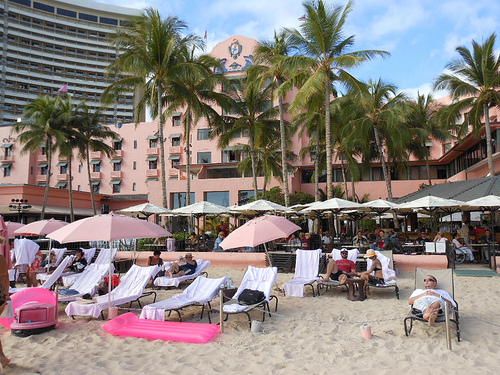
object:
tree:
[9, 95, 96, 224]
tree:
[100, 6, 240, 211]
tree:
[147, 43, 245, 206]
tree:
[388, 88, 470, 188]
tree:
[96, 0, 213, 213]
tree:
[57, 97, 122, 230]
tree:
[329, 70, 412, 205]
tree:
[271, 0, 393, 201]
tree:
[205, 66, 293, 198]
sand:
[0, 267, 500, 375]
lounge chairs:
[206, 265, 280, 332]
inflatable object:
[98, 310, 220, 342]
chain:
[64, 263, 163, 322]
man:
[405, 274, 457, 326]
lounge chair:
[401, 266, 461, 341]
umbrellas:
[44, 213, 174, 245]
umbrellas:
[113, 202, 175, 217]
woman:
[357, 247, 384, 295]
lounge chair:
[363, 249, 401, 301]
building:
[0, 34, 497, 205]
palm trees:
[430, 28, 500, 180]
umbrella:
[216, 212, 304, 250]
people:
[320, 248, 357, 285]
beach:
[0, 267, 498, 374]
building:
[1, 1, 148, 127]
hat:
[362, 249, 376, 259]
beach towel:
[280, 249, 322, 298]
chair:
[280, 246, 325, 298]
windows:
[107, 160, 123, 171]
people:
[364, 228, 389, 252]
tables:
[470, 243, 498, 248]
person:
[450, 233, 479, 266]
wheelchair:
[446, 245, 467, 264]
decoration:
[211, 53, 255, 76]